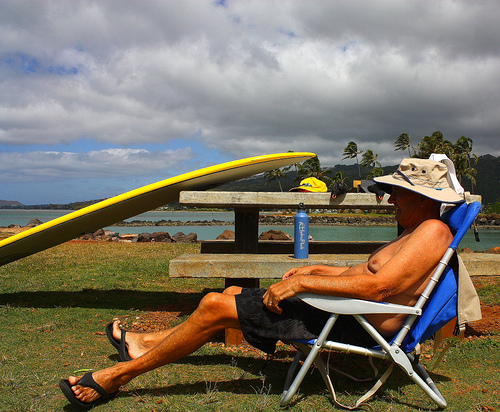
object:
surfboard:
[0, 152, 318, 267]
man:
[61, 157, 455, 403]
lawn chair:
[280, 200, 482, 408]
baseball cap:
[289, 177, 327, 193]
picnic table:
[179, 191, 481, 255]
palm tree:
[264, 167, 283, 192]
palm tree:
[294, 155, 331, 180]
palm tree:
[342, 141, 362, 180]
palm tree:
[363, 151, 385, 178]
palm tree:
[394, 133, 410, 157]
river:
[0, 208, 499, 250]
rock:
[137, 232, 152, 242]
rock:
[152, 231, 174, 241]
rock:
[172, 232, 187, 242]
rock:
[188, 233, 197, 242]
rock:
[216, 230, 235, 239]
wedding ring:
[268, 301, 272, 303]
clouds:
[0, 0, 499, 167]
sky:
[0, 0, 499, 206]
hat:
[372, 157, 463, 204]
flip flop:
[60, 372, 118, 409]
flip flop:
[106, 322, 132, 361]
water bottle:
[294, 203, 308, 259]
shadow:
[0, 289, 199, 312]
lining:
[296, 202, 479, 345]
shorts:
[234, 286, 378, 354]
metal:
[280, 247, 453, 407]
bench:
[169, 252, 500, 347]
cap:
[298, 203, 304, 210]